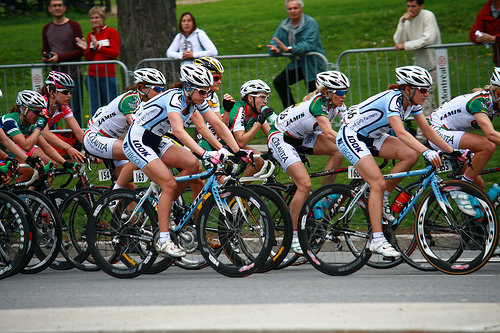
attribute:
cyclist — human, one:
[7, 33, 498, 275]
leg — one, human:
[87, 77, 101, 115]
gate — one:
[226, 54, 416, 106]